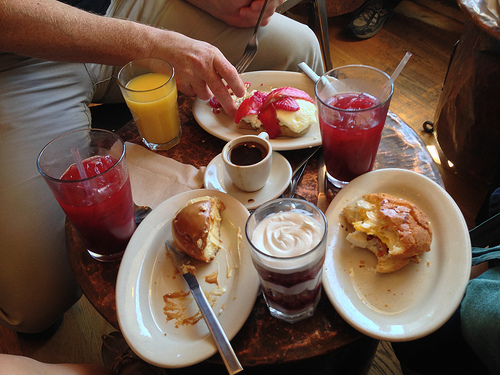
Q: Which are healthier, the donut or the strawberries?
A: The strawberries are healthier than the donut.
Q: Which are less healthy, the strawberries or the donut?
A: The donut are less healthy than the strawberries.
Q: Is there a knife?
A: Yes, there is a knife.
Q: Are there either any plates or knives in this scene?
A: Yes, there is a knife.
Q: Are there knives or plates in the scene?
A: Yes, there is a knife.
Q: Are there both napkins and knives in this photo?
A: Yes, there are both a knife and a napkin.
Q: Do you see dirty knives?
A: Yes, there is a dirty knife.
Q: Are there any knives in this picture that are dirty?
A: Yes, there is a knife that is dirty.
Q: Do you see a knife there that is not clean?
A: Yes, there is a dirty knife.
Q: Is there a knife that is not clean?
A: Yes, there is a dirty knife.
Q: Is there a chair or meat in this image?
A: No, there are no chairs or meat.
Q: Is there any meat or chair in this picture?
A: No, there are no chairs or meat.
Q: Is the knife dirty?
A: Yes, the knife is dirty.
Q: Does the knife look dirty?
A: Yes, the knife is dirty.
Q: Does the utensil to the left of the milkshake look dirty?
A: Yes, the knife is dirty.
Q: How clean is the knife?
A: The knife is dirty.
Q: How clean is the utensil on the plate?
A: The knife is dirty.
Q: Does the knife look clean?
A: No, the knife is dirty.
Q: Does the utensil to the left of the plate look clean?
A: No, the knife is dirty.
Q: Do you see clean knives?
A: No, there is a knife but it is dirty.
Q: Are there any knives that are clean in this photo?
A: No, there is a knife but it is dirty.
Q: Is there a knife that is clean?
A: No, there is a knife but it is dirty.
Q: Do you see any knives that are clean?
A: No, there is a knife but it is dirty.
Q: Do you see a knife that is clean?
A: No, there is a knife but it is dirty.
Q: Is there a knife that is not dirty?
A: No, there is a knife but it is dirty.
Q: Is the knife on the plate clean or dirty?
A: The knife is dirty.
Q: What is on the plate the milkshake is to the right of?
A: The knife is on the plate.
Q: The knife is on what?
A: The knife is on the plate.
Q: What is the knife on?
A: The knife is on the plate.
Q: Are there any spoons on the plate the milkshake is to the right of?
A: No, there is a knife on the plate.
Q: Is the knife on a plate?
A: Yes, the knife is on a plate.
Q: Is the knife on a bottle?
A: No, the knife is on a plate.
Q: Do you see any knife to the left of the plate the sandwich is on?
A: Yes, there is a knife to the left of the plate.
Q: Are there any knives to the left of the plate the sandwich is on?
A: Yes, there is a knife to the left of the plate.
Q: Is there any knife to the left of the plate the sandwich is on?
A: Yes, there is a knife to the left of the plate.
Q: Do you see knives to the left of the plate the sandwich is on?
A: Yes, there is a knife to the left of the plate.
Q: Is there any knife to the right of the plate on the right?
A: No, the knife is to the left of the plate.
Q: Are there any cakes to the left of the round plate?
A: No, there is a knife to the left of the plate.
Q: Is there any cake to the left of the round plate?
A: No, there is a knife to the left of the plate.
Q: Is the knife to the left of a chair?
A: No, the knife is to the left of a plate.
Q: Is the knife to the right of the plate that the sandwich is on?
A: No, the knife is to the left of the plate.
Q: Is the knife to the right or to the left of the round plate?
A: The knife is to the left of the plate.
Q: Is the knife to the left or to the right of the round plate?
A: The knife is to the left of the plate.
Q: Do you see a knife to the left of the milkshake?
A: Yes, there is a knife to the left of the milkshake.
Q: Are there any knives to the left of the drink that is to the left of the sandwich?
A: Yes, there is a knife to the left of the milkshake.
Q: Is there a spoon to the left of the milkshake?
A: No, there is a knife to the left of the milkshake.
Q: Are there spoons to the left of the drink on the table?
A: No, there is a knife to the left of the milkshake.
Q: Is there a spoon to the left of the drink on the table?
A: No, there is a knife to the left of the milkshake.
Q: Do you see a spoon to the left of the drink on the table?
A: No, there is a knife to the left of the milkshake.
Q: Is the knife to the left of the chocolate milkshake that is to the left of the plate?
A: Yes, the knife is to the left of the milkshake.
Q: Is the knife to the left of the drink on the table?
A: Yes, the knife is to the left of the milkshake.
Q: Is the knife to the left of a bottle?
A: No, the knife is to the left of the milkshake.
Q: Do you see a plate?
A: Yes, there is a plate.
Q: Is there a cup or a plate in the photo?
A: Yes, there is a plate.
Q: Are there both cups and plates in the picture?
A: Yes, there are both a plate and a cup.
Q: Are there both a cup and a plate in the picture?
A: Yes, there are both a plate and a cup.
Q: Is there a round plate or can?
A: Yes, there is a round plate.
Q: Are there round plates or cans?
A: Yes, there is a round plate.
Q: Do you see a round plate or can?
A: Yes, there is a round plate.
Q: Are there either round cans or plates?
A: Yes, there is a round plate.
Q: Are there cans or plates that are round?
A: Yes, the plate is round.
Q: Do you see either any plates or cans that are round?
A: Yes, the plate is round.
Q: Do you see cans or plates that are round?
A: Yes, the plate is round.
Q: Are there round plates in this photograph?
A: Yes, there is a round plate.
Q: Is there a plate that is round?
A: Yes, there is a plate that is round.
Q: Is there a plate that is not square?
A: Yes, there is a round plate.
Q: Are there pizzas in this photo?
A: No, there are no pizzas.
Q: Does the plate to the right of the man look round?
A: Yes, the plate is round.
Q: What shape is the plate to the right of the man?
A: The plate is round.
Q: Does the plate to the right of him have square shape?
A: No, the plate is round.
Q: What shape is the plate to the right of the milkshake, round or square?
A: The plate is round.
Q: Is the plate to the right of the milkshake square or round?
A: The plate is round.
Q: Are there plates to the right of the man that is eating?
A: Yes, there is a plate to the right of the man.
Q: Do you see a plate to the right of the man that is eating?
A: Yes, there is a plate to the right of the man.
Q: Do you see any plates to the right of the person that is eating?
A: Yes, there is a plate to the right of the man.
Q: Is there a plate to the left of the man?
A: No, the plate is to the right of the man.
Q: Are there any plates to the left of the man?
A: No, the plate is to the right of the man.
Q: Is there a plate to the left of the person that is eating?
A: No, the plate is to the right of the man.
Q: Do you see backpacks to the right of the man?
A: No, there is a plate to the right of the man.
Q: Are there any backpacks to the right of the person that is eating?
A: No, there is a plate to the right of the man.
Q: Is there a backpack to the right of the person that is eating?
A: No, there is a plate to the right of the man.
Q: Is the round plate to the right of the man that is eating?
A: Yes, the plate is to the right of the man.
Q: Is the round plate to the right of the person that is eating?
A: Yes, the plate is to the right of the man.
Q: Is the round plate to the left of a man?
A: No, the plate is to the right of a man.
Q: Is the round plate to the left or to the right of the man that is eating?
A: The plate is to the right of the man.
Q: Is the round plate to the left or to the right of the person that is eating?
A: The plate is to the right of the man.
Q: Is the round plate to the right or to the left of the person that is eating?
A: The plate is to the right of the man.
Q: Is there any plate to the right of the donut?
A: Yes, there is a plate to the right of the donut.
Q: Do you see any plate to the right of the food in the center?
A: Yes, there is a plate to the right of the donut.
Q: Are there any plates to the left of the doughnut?
A: No, the plate is to the right of the doughnut.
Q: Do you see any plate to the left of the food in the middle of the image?
A: No, the plate is to the right of the doughnut.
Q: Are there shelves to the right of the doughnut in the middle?
A: No, there is a plate to the right of the donut.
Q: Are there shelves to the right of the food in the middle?
A: No, there is a plate to the right of the donut.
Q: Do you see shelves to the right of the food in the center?
A: No, there is a plate to the right of the donut.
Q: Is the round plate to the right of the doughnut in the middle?
A: Yes, the plate is to the right of the doughnut.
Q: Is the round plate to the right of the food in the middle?
A: Yes, the plate is to the right of the doughnut.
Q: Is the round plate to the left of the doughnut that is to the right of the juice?
A: No, the plate is to the right of the donut.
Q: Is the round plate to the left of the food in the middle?
A: No, the plate is to the right of the donut.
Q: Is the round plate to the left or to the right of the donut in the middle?
A: The plate is to the right of the donut.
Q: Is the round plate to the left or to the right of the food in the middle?
A: The plate is to the right of the donut.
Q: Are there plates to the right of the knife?
A: Yes, there is a plate to the right of the knife.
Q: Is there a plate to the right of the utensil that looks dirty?
A: Yes, there is a plate to the right of the knife.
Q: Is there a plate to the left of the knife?
A: No, the plate is to the right of the knife.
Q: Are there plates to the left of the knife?
A: No, the plate is to the right of the knife.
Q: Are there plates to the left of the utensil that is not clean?
A: No, the plate is to the right of the knife.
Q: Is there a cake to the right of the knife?
A: No, there is a plate to the right of the knife.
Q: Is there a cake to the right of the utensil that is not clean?
A: No, there is a plate to the right of the knife.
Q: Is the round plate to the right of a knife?
A: Yes, the plate is to the right of a knife.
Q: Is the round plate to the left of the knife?
A: No, the plate is to the right of the knife.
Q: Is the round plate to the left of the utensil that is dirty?
A: No, the plate is to the right of the knife.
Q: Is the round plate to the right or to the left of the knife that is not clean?
A: The plate is to the right of the knife.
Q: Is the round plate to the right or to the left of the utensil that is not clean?
A: The plate is to the right of the knife.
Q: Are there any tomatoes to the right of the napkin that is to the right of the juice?
A: No, there is a plate to the right of the napkin.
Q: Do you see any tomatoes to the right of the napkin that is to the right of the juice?
A: No, there is a plate to the right of the napkin.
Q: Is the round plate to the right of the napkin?
A: Yes, the plate is to the right of the napkin.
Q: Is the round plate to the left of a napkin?
A: No, the plate is to the right of a napkin.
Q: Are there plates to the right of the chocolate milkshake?
A: Yes, there is a plate to the right of the milkshake.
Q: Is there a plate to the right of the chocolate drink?
A: Yes, there is a plate to the right of the milkshake.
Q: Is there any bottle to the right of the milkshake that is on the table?
A: No, there is a plate to the right of the milkshake.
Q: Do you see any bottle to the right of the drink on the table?
A: No, there is a plate to the right of the milkshake.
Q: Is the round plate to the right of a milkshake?
A: Yes, the plate is to the right of a milkshake.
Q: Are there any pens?
A: No, there are no pens.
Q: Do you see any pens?
A: No, there are no pens.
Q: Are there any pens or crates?
A: No, there are no pens or crates.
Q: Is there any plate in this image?
A: Yes, there is a plate.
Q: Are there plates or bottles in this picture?
A: Yes, there is a plate.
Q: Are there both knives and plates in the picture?
A: Yes, there are both a plate and a knife.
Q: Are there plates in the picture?
A: Yes, there is a plate.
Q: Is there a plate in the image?
A: Yes, there is a plate.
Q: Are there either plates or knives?
A: Yes, there is a plate.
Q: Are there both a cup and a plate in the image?
A: Yes, there are both a plate and a cup.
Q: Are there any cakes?
A: No, there are no cakes.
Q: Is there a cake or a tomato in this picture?
A: No, there are no cakes or tomatoes.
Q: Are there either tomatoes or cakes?
A: No, there are no cakes or tomatoes.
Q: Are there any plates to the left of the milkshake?
A: Yes, there is a plate to the left of the milkshake.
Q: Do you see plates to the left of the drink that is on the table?
A: Yes, there is a plate to the left of the milkshake.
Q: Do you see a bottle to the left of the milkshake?
A: No, there is a plate to the left of the milkshake.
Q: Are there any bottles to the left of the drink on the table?
A: No, there is a plate to the left of the milkshake.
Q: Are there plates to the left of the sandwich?
A: Yes, there is a plate to the left of the sandwich.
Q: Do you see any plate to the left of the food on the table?
A: Yes, there is a plate to the left of the sandwich.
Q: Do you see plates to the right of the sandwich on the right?
A: No, the plate is to the left of the sandwich.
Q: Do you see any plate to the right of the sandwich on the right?
A: No, the plate is to the left of the sandwich.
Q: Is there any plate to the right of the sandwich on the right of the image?
A: No, the plate is to the left of the sandwich.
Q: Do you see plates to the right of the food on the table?
A: No, the plate is to the left of the sandwich.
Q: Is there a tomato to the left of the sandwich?
A: No, there is a plate to the left of the sandwich.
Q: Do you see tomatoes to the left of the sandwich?
A: No, there is a plate to the left of the sandwich.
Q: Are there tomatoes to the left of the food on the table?
A: No, there is a plate to the left of the sandwich.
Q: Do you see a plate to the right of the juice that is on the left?
A: Yes, there is a plate to the right of the juice.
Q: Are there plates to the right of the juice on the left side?
A: Yes, there is a plate to the right of the juice.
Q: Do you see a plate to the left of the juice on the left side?
A: No, the plate is to the right of the juice.